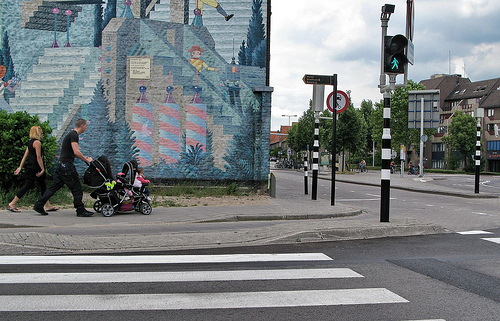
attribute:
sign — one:
[292, 83, 412, 163]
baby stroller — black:
[79, 152, 156, 218]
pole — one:
[311, 82, 324, 201]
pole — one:
[368, 73, 410, 219]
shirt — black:
[55, 124, 85, 173]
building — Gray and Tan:
[407, 75, 444, 132]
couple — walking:
[7, 120, 94, 219]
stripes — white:
[1, 250, 448, 319]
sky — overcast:
[271, 0, 499, 131]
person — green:
[391, 55, 398, 68]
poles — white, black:
[298, 35, 488, 229]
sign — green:
[382, 42, 403, 67]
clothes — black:
[15, 138, 47, 194]